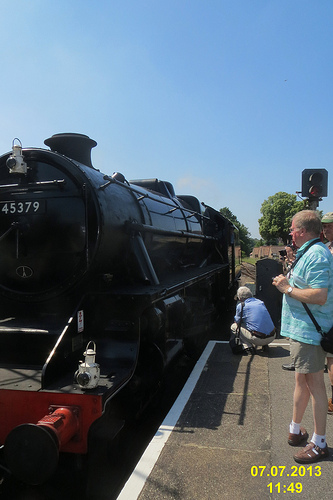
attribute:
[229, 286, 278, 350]
man — in a blue shirt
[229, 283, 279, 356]
gray man — sight seeing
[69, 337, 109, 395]
white lamp — on the engine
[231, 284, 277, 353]
man — examines the engine, with a satchel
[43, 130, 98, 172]
stack — of a steam engine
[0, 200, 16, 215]
first two/numbers — in front of train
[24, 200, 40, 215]
last two/numbers — in front of train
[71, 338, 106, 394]
light structure — white, in front of train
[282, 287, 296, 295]
watch —  wrist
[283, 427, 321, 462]
sandals. — brown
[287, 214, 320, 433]
man —  wrist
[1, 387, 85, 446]
paint — Red 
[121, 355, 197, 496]
line — boundary, White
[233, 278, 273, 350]
person — standing.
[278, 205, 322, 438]
person — standing.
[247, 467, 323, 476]
date — stamped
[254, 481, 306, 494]
time — stamped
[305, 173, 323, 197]
light — Traffic, above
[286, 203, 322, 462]
person — looking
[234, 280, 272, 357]
man — crouching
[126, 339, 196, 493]
line — blue, boundary, white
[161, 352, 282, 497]
platform — concrete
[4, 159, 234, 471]
train — red, black, leaving, paint 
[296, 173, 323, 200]
light — traffic, track , train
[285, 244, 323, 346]
bag —  shoulder 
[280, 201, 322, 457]
man — older, wearing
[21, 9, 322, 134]
sky —  blue, clear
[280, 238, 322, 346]
shirt — polo, striped, teal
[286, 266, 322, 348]
bag — carried, hand , black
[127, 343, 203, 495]
line — painted, white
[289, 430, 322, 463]
sandals — brown, mens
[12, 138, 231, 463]
train — black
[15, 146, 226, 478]
train — red, bumper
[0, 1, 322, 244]
skies — blue, clear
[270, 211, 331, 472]
man — one, old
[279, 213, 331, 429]
man — one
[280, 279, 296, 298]
watch — one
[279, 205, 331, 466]
man — one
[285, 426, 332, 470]
sandals — some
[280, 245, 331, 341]
shirt — blue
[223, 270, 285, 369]
man — kneeling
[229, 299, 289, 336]
shirt — blue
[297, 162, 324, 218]
signal lights — black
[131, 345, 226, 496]
lines — white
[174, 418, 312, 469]
line — jagged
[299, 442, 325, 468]
shoes — brown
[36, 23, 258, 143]
skies — clear, blue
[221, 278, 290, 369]
person — stooping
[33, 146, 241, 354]
train — large, black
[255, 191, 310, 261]
trees — large, clump, green